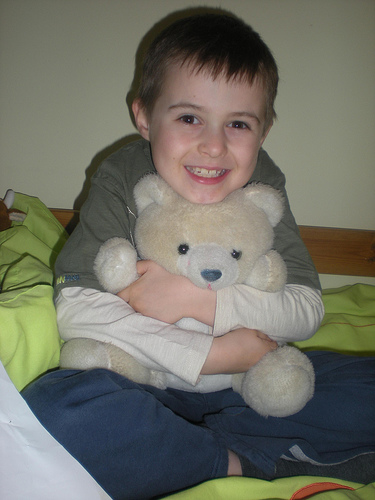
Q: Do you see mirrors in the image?
A: No, there are no mirrors.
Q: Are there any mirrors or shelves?
A: No, there are no mirrors or shelves.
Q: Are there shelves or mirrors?
A: No, there are no mirrors or shelves.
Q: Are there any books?
A: No, there are no books.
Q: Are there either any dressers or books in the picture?
A: No, there are no books or dressers.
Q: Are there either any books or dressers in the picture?
A: No, there are no books or dressers.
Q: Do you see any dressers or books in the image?
A: No, there are no books or dressers.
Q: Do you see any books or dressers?
A: No, there are no books or dressers.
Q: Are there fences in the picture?
A: No, there are no fences.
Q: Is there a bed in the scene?
A: Yes, there is a bed.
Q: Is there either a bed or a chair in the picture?
A: Yes, there is a bed.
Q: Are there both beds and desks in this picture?
A: No, there is a bed but no desks.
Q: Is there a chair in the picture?
A: No, there are no chairs.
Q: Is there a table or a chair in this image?
A: No, there are no chairs or tables.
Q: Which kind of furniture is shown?
A: The furniture is a bed.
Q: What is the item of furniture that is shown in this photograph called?
A: The piece of furniture is a bed.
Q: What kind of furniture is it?
A: The piece of furniture is a bed.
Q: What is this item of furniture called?
A: This is a bed.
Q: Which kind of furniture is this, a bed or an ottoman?
A: This is a bed.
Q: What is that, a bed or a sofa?
A: That is a bed.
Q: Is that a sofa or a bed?
A: That is a bed.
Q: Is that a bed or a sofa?
A: That is a bed.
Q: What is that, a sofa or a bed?
A: That is a bed.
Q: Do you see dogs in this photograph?
A: No, there are no dogs.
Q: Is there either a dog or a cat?
A: No, there are no dogs or cats.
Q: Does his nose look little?
A: Yes, the nose is little.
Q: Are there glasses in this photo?
A: No, there are no glasses.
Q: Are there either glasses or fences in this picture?
A: No, there are no glasses or fences.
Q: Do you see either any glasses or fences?
A: No, there are no glasses or fences.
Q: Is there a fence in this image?
A: No, there are no fences.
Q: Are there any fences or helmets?
A: No, there are no fences or helmets.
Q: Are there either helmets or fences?
A: No, there are no fences or helmets.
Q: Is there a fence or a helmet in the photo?
A: No, there are no fences or helmets.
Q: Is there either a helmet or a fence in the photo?
A: No, there are no fences or helmets.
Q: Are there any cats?
A: No, there are no cats.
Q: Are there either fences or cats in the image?
A: No, there are no cats or fences.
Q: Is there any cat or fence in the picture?
A: No, there are no cats or fences.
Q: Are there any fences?
A: No, there are no fences.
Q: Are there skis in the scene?
A: No, there are no skis.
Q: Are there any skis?
A: No, there are no skis.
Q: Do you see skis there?
A: No, there are no skis.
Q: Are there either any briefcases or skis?
A: No, there are no skis or briefcases.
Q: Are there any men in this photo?
A: No, there are no men.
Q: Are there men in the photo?
A: No, there are no men.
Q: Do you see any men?
A: No, there are no men.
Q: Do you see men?
A: No, there are no men.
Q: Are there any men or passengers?
A: No, there are no men or passengers.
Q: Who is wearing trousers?
A: The boy is wearing trousers.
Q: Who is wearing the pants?
A: The boy is wearing trousers.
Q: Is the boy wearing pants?
A: Yes, the boy is wearing pants.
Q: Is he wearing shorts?
A: No, the boy is wearing pants.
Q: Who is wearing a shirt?
A: The boy is wearing a shirt.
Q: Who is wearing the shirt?
A: The boy is wearing a shirt.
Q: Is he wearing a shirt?
A: Yes, the boy is wearing a shirt.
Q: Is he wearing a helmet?
A: No, the boy is wearing a shirt.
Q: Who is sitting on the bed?
A: The boy is sitting on the bed.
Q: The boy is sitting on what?
A: The boy is sitting on the bed.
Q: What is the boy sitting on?
A: The boy is sitting on the bed.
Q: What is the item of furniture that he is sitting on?
A: The piece of furniture is a bed.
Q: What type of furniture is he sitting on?
A: The boy is sitting on the bed.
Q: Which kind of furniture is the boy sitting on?
A: The boy is sitting on the bed.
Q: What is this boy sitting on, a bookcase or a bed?
A: The boy is sitting on a bed.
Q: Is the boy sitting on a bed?
A: Yes, the boy is sitting on a bed.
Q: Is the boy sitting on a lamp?
A: No, the boy is sitting on a bed.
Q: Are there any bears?
A: Yes, there is a bear.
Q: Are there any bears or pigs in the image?
A: Yes, there is a bear.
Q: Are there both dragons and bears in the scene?
A: No, there is a bear but no dragons.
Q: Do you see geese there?
A: No, there are no geese.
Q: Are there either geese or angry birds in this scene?
A: No, there are no geese or angry birds.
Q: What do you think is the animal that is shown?
A: The animal is a bear.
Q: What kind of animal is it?
A: The animal is a bear.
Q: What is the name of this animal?
A: This is a bear.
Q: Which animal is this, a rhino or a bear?
A: This is a bear.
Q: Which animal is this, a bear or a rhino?
A: This is a bear.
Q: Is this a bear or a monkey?
A: This is a bear.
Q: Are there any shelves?
A: No, there are no shelves.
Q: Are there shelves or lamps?
A: No, there are no shelves or lamps.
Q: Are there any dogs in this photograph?
A: No, there are no dogs.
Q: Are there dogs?
A: No, there are no dogs.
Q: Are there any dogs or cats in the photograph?
A: No, there are no dogs or cats.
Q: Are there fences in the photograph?
A: No, there are no fences.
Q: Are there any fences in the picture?
A: No, there are no fences.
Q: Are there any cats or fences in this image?
A: No, there are no fences or cats.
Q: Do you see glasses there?
A: No, there are no glasses.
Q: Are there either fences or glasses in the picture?
A: No, there are no glasses or fences.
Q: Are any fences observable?
A: No, there are no fences.